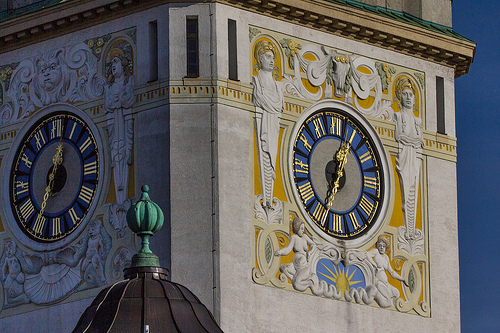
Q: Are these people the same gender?
A: Yes, all the people are female.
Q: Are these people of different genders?
A: No, all the people are female.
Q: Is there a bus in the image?
A: No, there are no buses.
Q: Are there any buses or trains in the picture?
A: No, there are no buses or trains.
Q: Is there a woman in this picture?
A: Yes, there is a woman.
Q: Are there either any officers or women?
A: Yes, there is a woman.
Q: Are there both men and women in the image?
A: No, there is a woman but no men.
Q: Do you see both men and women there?
A: No, there is a woman but no men.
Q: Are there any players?
A: No, there are no players.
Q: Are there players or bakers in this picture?
A: No, there are no players or bakers.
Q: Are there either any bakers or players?
A: No, there are no players or bakers.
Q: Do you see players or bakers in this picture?
A: No, there are no players or bakers.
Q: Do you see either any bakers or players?
A: No, there are no players or bakers.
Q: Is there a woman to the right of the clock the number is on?
A: Yes, there is a woman to the right of the clock.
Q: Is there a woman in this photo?
A: Yes, there is a woman.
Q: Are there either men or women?
A: Yes, there is a woman.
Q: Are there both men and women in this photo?
A: No, there is a woman but no men.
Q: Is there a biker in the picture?
A: No, there are no bikers.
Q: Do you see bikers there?
A: No, there are no bikers.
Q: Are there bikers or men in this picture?
A: No, there are no bikers or men.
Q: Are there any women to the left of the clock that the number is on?
A: Yes, there is a woman to the left of the clock.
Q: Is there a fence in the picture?
A: No, there are no fences.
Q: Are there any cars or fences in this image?
A: No, there are no fences or cars.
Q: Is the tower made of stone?
A: Yes, the tower is made of stone.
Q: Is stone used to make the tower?
A: Yes, the tower is made of stone.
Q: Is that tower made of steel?
A: No, the tower is made of stone.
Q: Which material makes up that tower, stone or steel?
A: The tower is made of stone.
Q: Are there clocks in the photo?
A: Yes, there is a clock.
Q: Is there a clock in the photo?
A: Yes, there is a clock.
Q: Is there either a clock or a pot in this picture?
A: Yes, there is a clock.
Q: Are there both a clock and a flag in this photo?
A: No, there is a clock but no flags.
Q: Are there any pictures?
A: No, there are no pictures.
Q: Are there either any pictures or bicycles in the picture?
A: No, there are no pictures or bicycles.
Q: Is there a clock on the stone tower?
A: Yes, there is a clock on the tower.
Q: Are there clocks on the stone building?
A: Yes, there is a clock on the tower.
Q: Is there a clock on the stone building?
A: Yes, there is a clock on the tower.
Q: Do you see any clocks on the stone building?
A: Yes, there is a clock on the tower.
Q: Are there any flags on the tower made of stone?
A: No, there is a clock on the tower.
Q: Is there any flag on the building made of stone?
A: No, there is a clock on the tower.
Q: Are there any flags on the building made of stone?
A: No, there is a clock on the tower.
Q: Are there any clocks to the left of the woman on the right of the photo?
A: Yes, there is a clock to the left of the woman.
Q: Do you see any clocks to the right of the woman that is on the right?
A: No, the clock is to the left of the woman.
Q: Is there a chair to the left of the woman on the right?
A: No, there is a clock to the left of the woman.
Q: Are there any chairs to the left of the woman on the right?
A: No, there is a clock to the left of the woman.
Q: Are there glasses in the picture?
A: No, there are no glasses.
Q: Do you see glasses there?
A: No, there are no glasses.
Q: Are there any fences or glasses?
A: No, there are no glasses or fences.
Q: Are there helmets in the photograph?
A: No, there are no helmets.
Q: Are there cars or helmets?
A: No, there are no helmets or cars.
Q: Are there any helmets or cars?
A: No, there are no helmets or cars.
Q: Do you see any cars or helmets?
A: No, there are no helmets or cars.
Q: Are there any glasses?
A: No, there are no glasses.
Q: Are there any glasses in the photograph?
A: No, there are no glasses.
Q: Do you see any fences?
A: No, there are no fences.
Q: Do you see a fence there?
A: No, there are no fences.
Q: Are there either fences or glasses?
A: No, there are no fences or glasses.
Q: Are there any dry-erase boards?
A: No, there are no dry-erase boards.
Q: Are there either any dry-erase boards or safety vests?
A: No, there are no dry-erase boards or safety vests.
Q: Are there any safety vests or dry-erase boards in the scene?
A: No, there are no dry-erase boards or safety vests.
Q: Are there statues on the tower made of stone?
A: Yes, there is a statue on the tower.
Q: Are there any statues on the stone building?
A: Yes, there is a statue on the tower.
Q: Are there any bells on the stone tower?
A: No, there is a statue on the tower.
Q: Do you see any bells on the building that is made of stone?
A: No, there is a statue on the tower.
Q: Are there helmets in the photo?
A: No, there are no helmets.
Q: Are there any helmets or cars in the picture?
A: No, there are no helmets or cars.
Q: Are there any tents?
A: No, there are no tents.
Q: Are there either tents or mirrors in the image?
A: No, there are no tents or mirrors.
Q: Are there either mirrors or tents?
A: No, there are no tents or mirrors.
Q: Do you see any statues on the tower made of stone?
A: Yes, there is a statue on the tower.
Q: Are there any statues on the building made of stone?
A: Yes, there is a statue on the tower.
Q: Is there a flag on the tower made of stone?
A: No, there is a statue on the tower.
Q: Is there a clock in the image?
A: Yes, there is a clock.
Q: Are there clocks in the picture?
A: Yes, there is a clock.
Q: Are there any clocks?
A: Yes, there is a clock.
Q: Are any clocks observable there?
A: Yes, there is a clock.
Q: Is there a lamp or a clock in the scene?
A: Yes, there is a clock.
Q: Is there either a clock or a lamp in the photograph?
A: Yes, there is a clock.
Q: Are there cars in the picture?
A: No, there are no cars.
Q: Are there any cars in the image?
A: No, there are no cars.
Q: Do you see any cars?
A: No, there are no cars.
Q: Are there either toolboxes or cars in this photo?
A: No, there are no cars or toolboxes.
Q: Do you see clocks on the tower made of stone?
A: Yes, there is a clock on the tower.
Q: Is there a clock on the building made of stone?
A: Yes, there is a clock on the tower.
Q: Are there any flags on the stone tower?
A: No, there is a clock on the tower.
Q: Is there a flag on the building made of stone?
A: No, there is a clock on the tower.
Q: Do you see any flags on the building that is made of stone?
A: No, there is a clock on the tower.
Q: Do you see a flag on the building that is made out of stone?
A: No, there is a clock on the tower.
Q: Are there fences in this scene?
A: No, there are no fences.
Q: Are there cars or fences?
A: No, there are no fences or cars.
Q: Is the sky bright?
A: Yes, the sky is bright.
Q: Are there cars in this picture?
A: No, there are no cars.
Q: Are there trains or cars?
A: No, there are no cars or trains.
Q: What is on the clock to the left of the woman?
A: The number is on the clock.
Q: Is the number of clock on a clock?
A: Yes, the number is on a clock.